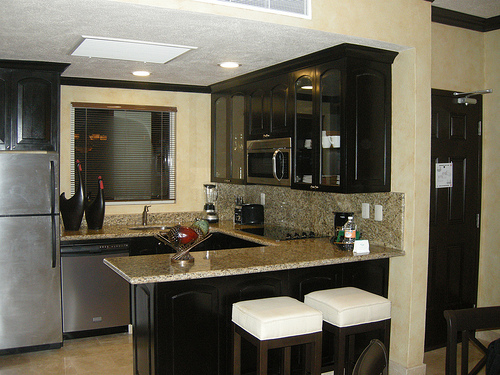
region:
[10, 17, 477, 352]
kitchen in an hotel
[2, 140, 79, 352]
stainless steel refrigerator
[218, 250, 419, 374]
two wooden bar stools with white cushions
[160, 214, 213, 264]
two decorative acorns on a stand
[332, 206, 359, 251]
water bottle on a kitchen counter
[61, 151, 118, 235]
two decorative hens on a kitchen counter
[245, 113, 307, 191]
stainless steel microwave in a kitchen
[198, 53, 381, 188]
wood and glass cabinets in a kitchen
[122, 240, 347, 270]
granite kitchen countertops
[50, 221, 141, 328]
stainless steel dishwasher in a kitchen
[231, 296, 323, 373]
a white padded stool with wooden legs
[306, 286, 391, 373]
a white padded stool with wooden legs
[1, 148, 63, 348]
a stainless steel refridgerator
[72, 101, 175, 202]
a window in a kitchen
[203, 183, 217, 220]
a blender on the kitchen counter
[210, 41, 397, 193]
cabinets and microwave in a kitchen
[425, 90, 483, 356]
a dark brown door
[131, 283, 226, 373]
wooden section of a counter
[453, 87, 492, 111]
a metal door hinge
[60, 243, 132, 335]
stainless steel diswasher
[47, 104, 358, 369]
the kitchen is tiled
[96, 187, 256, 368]
the kitchen is tiled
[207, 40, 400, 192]
black cabinets hanging on the wall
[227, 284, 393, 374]
black stools with white cushions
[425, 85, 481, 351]
black door with white sign on it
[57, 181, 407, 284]
brown and white granite countertop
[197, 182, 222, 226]
black and silver blender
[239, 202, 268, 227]
small black toaster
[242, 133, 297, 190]
stainless steel and black microwave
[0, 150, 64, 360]
stainless steel refridgerator with black handles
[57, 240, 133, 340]
stainless steel and black dishwasher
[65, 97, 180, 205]
window above the kitchen sink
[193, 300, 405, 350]
two white stools at kitchen bar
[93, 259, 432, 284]
kitchen bar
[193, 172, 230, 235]
blender on top of counter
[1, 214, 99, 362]
stainless steel refrigerator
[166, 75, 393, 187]
kitchen cabinets and microwave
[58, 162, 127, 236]
two black duck statues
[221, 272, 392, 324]
two stools sitting at kitchen counter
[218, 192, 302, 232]
toaster on top of kitchen counter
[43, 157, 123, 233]
dual mallard kitchen decor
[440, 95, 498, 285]
front door to house